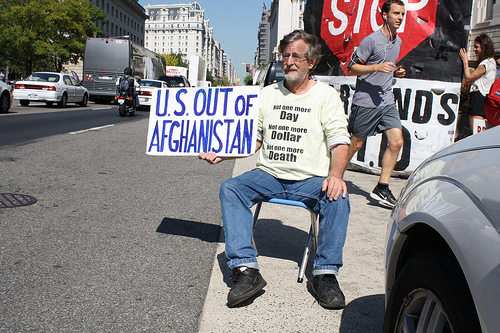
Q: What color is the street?
A: Gray.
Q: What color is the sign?
A: White and blue.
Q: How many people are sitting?
A: One.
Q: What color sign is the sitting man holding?
A: White with blue writing.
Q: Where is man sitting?
A: On a chair.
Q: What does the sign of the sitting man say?
A: U.S. OUT OF AFGHANISTAN.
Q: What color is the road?
A: Gray.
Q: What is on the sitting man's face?
A: Glasses.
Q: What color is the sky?
A: Blue.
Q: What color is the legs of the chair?
A: Silver.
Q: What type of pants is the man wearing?
A: Jeans.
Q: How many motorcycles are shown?
A: One.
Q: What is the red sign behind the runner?
A: A stop sign.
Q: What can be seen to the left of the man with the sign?
A: Traffic.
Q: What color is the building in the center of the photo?
A: White.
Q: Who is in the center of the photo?
A: A man with a sign on a street.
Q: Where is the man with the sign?
A: Sitting on a chair on a sidewalk.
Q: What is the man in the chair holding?
A: A sign with blue lettering.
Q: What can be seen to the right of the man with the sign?
A: The front of a vehicle.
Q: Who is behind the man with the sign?
A: A jogger.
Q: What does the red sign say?
A: Stop.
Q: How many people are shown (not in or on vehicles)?
A: 3.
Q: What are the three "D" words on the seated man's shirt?
A: Day, dollar, death.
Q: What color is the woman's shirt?
A: White.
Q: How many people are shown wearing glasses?
A: 1.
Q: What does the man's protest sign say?
A: U.S. out of Afghanistan.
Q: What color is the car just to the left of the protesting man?
A: White.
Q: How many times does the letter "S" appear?
A: 4.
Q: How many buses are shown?
A: 1.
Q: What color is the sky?
A: Blue.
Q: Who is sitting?
A: A man.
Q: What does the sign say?
A: "U.S. OUT OF AFGHANISTAN".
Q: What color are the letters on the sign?
A: Blue.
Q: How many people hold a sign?
A: One.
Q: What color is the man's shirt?
A: White.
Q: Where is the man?
A: On the sidewalk.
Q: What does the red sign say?
A: Stop.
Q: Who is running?
A: A man.